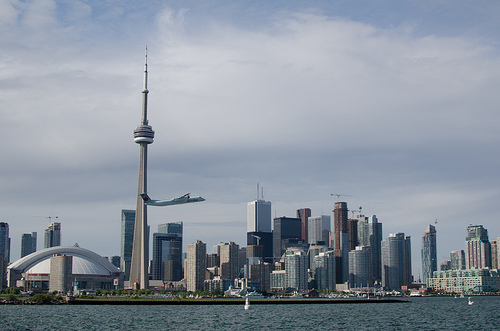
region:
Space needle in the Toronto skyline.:
[123, 41, 162, 300]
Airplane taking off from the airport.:
[136, 183, 231, 225]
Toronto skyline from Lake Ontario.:
[5, 34, 497, 328]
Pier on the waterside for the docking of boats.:
[72, 288, 414, 310]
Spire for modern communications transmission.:
[126, 36, 161, 125]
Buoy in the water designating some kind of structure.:
[236, 288, 265, 314]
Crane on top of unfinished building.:
[327, 185, 356, 207]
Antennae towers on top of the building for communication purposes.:
[249, 172, 274, 207]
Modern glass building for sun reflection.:
[152, 229, 186, 281]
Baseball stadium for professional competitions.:
[1, 239, 127, 312]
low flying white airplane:
[134, 184, 216, 219]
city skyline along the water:
[19, 36, 471, 314]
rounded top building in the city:
[8, 233, 130, 298]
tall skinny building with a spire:
[126, 33, 168, 297]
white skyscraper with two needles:
[234, 184, 279, 239]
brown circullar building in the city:
[325, 184, 364, 272]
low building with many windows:
[421, 259, 496, 296]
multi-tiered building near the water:
[411, 214, 448, 324]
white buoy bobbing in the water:
[237, 288, 254, 318]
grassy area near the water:
[79, 285, 193, 315]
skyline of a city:
[9, 176, 498, 297]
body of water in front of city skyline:
[10, 306, 486, 329]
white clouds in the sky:
[221, 33, 487, 135]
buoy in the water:
[242, 294, 254, 314]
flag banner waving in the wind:
[139, 185, 211, 212]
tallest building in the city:
[120, 42, 160, 294]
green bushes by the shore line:
[13, 292, 63, 300]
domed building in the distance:
[12, 241, 124, 296]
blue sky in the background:
[362, 0, 463, 19]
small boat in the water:
[462, 294, 484, 309]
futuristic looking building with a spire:
[108, 31, 170, 307]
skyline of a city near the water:
[226, 183, 487, 298]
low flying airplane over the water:
[136, 174, 215, 227]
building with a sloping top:
[5, 247, 123, 295]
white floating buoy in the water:
[238, 292, 253, 317]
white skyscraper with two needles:
[236, 177, 281, 239]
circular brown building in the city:
[324, 191, 354, 260]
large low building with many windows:
[426, 265, 493, 293]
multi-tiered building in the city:
[413, 216, 443, 297]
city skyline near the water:
[18, 27, 487, 316]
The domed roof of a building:
[16, 234, 121, 287]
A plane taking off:
[134, 181, 210, 211]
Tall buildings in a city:
[229, 185, 410, 304]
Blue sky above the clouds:
[406, 4, 489, 30]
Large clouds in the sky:
[214, 41, 470, 145]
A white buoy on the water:
[235, 293, 255, 311]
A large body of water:
[272, 301, 485, 326]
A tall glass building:
[150, 224, 194, 294]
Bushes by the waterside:
[10, 291, 57, 305]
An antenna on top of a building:
[327, 191, 354, 207]